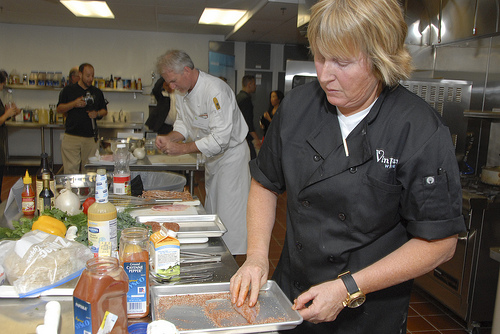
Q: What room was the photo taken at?
A: It was taken at the kitchen.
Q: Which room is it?
A: It is a kitchen.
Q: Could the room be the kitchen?
A: Yes, it is the kitchen.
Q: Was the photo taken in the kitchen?
A: Yes, it was taken in the kitchen.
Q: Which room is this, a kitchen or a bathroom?
A: It is a kitchen.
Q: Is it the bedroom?
A: No, it is the kitchen.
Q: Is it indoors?
A: Yes, it is indoors.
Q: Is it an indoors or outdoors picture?
A: It is indoors.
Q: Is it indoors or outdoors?
A: It is indoors.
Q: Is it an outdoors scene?
A: No, it is indoors.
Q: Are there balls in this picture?
A: No, there are no balls.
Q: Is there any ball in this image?
A: No, there are no balls.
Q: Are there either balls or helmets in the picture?
A: No, there are no balls or helmets.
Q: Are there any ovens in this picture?
A: Yes, there is an oven.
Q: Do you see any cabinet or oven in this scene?
A: Yes, there is an oven.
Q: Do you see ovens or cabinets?
A: Yes, there is an oven.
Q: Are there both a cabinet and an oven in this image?
A: No, there is an oven but no cabinets.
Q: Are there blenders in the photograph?
A: No, there are no blenders.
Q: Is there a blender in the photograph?
A: No, there are no blenders.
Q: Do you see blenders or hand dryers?
A: No, there are no blenders or hand dryers.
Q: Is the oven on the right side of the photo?
A: Yes, the oven is on the right of the image.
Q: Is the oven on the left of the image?
A: No, the oven is on the right of the image.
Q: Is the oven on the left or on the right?
A: The oven is on the right of the image.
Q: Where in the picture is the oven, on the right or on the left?
A: The oven is on the right of the image.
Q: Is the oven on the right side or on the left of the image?
A: The oven is on the right of the image.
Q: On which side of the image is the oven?
A: The oven is on the right of the image.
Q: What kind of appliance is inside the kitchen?
A: The appliance is an oven.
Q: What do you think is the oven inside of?
A: The oven is inside the kitchen.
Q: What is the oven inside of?
A: The oven is inside the kitchen.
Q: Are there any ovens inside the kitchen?
A: Yes, there is an oven inside the kitchen.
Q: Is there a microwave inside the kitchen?
A: No, there is an oven inside the kitchen.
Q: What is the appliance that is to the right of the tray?
A: The appliance is an oven.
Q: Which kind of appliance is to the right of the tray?
A: The appliance is an oven.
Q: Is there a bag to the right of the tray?
A: No, there is an oven to the right of the tray.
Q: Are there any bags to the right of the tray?
A: No, there is an oven to the right of the tray.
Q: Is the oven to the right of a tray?
A: Yes, the oven is to the right of a tray.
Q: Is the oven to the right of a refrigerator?
A: No, the oven is to the right of a tray.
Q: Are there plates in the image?
A: No, there are no plates.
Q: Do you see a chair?
A: No, there are no chairs.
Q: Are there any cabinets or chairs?
A: No, there are no chairs or cabinets.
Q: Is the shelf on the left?
A: Yes, the shelf is on the left of the image.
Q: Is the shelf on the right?
A: No, the shelf is on the left of the image.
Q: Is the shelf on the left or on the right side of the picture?
A: The shelf is on the left of the image.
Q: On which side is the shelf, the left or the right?
A: The shelf is on the left of the image.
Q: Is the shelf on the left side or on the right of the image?
A: The shelf is on the left of the image.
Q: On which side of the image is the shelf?
A: The shelf is on the left of the image.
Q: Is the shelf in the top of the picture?
A: Yes, the shelf is in the top of the image.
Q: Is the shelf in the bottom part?
A: No, the shelf is in the top of the image.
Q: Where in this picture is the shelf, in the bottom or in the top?
A: The shelf is in the top of the image.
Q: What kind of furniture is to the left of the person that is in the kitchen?
A: The piece of furniture is a shelf.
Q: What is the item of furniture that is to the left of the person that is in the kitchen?
A: The piece of furniture is a shelf.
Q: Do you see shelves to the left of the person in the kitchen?
A: Yes, there is a shelf to the left of the person.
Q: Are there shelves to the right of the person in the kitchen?
A: No, the shelf is to the left of the person.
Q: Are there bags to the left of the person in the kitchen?
A: No, there is a shelf to the left of the person.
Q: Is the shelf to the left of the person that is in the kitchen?
A: Yes, the shelf is to the left of the person.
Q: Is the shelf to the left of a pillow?
A: No, the shelf is to the left of the person.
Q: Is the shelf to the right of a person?
A: No, the shelf is to the left of a person.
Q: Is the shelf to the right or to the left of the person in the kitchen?
A: The shelf is to the left of the person.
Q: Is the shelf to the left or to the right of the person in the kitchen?
A: The shelf is to the left of the person.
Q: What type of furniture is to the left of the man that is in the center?
A: The piece of furniture is a shelf.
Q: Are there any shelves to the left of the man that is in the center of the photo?
A: Yes, there is a shelf to the left of the man.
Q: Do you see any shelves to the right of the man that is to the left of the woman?
A: No, the shelf is to the left of the man.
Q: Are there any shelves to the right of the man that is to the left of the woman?
A: No, the shelf is to the left of the man.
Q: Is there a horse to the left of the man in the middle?
A: No, there is a shelf to the left of the man.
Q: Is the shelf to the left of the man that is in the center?
A: Yes, the shelf is to the left of the man.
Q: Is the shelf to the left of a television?
A: No, the shelf is to the left of the man.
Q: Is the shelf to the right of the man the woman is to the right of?
A: No, the shelf is to the left of the man.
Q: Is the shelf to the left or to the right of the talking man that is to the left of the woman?
A: The shelf is to the left of the man.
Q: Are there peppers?
A: Yes, there is a pepper.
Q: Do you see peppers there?
A: Yes, there is a pepper.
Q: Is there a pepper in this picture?
A: Yes, there is a pepper.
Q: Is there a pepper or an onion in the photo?
A: Yes, there is a pepper.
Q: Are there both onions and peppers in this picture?
A: Yes, there are both a pepper and an onion.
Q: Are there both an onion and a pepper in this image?
A: Yes, there are both a pepper and an onion.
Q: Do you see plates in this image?
A: No, there are no plates.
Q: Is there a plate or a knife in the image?
A: No, there are no plates or knives.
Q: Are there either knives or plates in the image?
A: No, there are no plates or knives.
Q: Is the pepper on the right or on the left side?
A: The pepper is on the left of the image.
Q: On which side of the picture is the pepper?
A: The pepper is on the left of the image.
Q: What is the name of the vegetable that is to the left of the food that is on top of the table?
A: The vegetable is a pepper.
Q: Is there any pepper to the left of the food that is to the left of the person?
A: Yes, there is a pepper to the left of the food.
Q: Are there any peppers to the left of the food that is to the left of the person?
A: Yes, there is a pepper to the left of the food.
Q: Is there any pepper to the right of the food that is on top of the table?
A: No, the pepper is to the left of the food.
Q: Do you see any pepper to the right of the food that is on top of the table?
A: No, the pepper is to the left of the food.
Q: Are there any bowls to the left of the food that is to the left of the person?
A: No, there is a pepper to the left of the food.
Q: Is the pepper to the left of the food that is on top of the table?
A: Yes, the pepper is to the left of the food.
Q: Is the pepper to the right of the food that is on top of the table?
A: No, the pepper is to the left of the food.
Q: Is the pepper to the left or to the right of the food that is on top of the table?
A: The pepper is to the left of the food.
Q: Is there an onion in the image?
A: Yes, there is an onion.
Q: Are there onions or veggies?
A: Yes, there is an onion.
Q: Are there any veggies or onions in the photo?
A: Yes, there is an onion.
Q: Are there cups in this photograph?
A: No, there are no cups.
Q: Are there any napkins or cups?
A: No, there are no cups or napkins.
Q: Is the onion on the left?
A: Yes, the onion is on the left of the image.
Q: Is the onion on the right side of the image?
A: No, the onion is on the left of the image.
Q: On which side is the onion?
A: The onion is on the left of the image.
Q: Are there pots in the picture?
A: No, there are no pots.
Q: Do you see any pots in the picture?
A: No, there are no pots.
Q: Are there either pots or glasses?
A: No, there are no pots or glasses.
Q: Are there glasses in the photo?
A: No, there are no glasses.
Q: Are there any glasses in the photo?
A: No, there are no glasses.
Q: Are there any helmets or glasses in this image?
A: No, there are no glasses or helmets.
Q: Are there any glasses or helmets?
A: No, there are no glasses or helmets.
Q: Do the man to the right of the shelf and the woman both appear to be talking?
A: Yes, both the man and the woman are talking.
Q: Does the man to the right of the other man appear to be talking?
A: Yes, the man is talking.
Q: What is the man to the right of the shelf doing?
A: The man is talking.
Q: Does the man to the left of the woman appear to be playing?
A: No, the man is talking.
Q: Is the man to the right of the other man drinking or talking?
A: The man is talking.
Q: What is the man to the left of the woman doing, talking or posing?
A: The man is talking.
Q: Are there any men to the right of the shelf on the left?
A: Yes, there is a man to the right of the shelf.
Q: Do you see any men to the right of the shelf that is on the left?
A: Yes, there is a man to the right of the shelf.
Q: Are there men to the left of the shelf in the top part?
A: No, the man is to the right of the shelf.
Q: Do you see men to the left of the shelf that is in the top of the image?
A: No, the man is to the right of the shelf.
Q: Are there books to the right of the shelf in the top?
A: No, there is a man to the right of the shelf.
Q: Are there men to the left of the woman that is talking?
A: Yes, there is a man to the left of the woman.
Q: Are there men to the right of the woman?
A: No, the man is to the left of the woman.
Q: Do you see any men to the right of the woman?
A: No, the man is to the left of the woman.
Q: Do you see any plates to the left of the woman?
A: No, there is a man to the left of the woman.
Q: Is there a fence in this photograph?
A: No, there are no fences.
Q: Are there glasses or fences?
A: No, there are no fences or glasses.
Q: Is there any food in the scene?
A: Yes, there is food.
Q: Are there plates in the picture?
A: No, there are no plates.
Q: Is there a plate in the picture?
A: No, there are no plates.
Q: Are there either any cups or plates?
A: No, there are no plates or cups.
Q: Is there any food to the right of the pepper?
A: Yes, there is food to the right of the pepper.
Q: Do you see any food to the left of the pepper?
A: No, the food is to the right of the pepper.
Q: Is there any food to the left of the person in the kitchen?
A: Yes, there is food to the left of the person.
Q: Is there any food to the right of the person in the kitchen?
A: No, the food is to the left of the person.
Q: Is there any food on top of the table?
A: Yes, there is food on top of the table.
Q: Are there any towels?
A: No, there are no towels.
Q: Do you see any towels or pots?
A: No, there are no towels or pots.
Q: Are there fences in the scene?
A: No, there are no fences.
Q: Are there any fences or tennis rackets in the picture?
A: No, there are no fences or tennis rackets.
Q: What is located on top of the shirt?
A: The logo is on top of the shirt.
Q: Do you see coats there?
A: Yes, there is a coat.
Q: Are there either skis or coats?
A: Yes, there is a coat.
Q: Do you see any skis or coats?
A: Yes, there is a coat.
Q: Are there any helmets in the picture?
A: No, there are no helmets.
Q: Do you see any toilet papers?
A: No, there are no toilet papers.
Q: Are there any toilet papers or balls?
A: No, there are no toilet papers or balls.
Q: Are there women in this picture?
A: Yes, there is a woman.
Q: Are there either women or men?
A: Yes, there is a woman.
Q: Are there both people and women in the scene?
A: Yes, there are both a woman and a person.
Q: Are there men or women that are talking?
A: Yes, the woman is talking.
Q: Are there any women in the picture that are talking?
A: Yes, there is a woman that is talking.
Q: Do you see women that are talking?
A: Yes, there is a woman that is talking.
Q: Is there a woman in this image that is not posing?
A: Yes, there is a woman that is talking.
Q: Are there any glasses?
A: No, there are no glasses.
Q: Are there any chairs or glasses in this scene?
A: No, there are no glasses or chairs.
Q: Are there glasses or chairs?
A: No, there are no glasses or chairs.